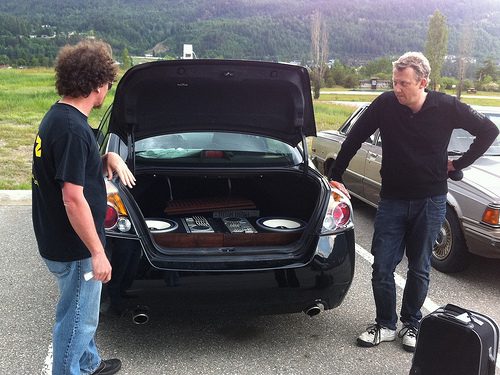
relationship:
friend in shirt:
[31, 39, 135, 375] [30, 99, 109, 261]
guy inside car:
[327, 49, 498, 352] [91, 58, 353, 326]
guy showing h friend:
[327, 49, 498, 352] [27, 39, 134, 372]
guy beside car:
[327, 49, 498, 352] [91, 58, 353, 326]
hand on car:
[319, 173, 360, 213] [19, 22, 377, 357]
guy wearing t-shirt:
[327, 49, 498, 352] [20, 92, 149, 292]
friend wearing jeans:
[31, 39, 135, 375] [40, 255, 113, 372]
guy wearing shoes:
[327, 49, 498, 352] [344, 311, 445, 375]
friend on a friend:
[31, 39, 135, 375] [31, 39, 135, 375]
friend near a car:
[31, 39, 135, 375] [91, 58, 353, 326]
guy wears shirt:
[327, 46, 498, 352] [30, 99, 144, 275]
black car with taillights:
[89, 58, 357, 323] [315, 186, 375, 246]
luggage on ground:
[410, 303, 497, 373] [324, 260, 494, 372]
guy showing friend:
[327, 49, 498, 352] [27, 39, 134, 372]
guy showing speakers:
[327, 49, 498, 352] [137, 200, 305, 245]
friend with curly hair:
[31, 39, 135, 375] [52, 36, 119, 99]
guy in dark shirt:
[327, 49, 498, 352] [322, 85, 499, 199]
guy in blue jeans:
[327, 49, 498, 352] [372, 195, 447, 325]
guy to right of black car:
[327, 49, 498, 352] [99, 52, 359, 323]